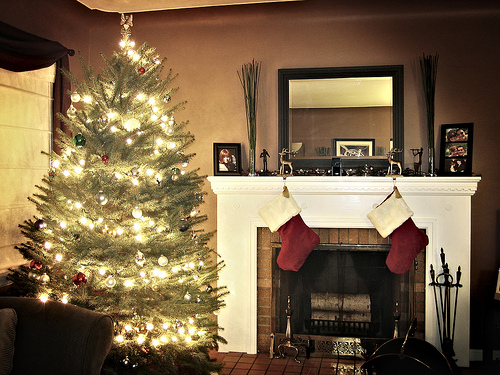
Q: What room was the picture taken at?
A: It was taken at the living room.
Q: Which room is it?
A: It is a living room.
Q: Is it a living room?
A: Yes, it is a living room.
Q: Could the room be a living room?
A: Yes, it is a living room.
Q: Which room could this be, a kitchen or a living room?
A: It is a living room.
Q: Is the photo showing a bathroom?
A: No, the picture is showing a living room.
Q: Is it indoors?
A: Yes, it is indoors.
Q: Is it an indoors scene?
A: Yes, it is indoors.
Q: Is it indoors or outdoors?
A: It is indoors.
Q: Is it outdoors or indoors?
A: It is indoors.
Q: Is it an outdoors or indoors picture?
A: It is indoors.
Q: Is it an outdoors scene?
A: No, it is indoors.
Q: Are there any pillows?
A: No, there are no pillows.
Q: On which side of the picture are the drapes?
A: The drapes are on the left of the image.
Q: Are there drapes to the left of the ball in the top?
A: Yes, there are drapes to the left of the ball.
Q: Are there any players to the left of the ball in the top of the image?
A: No, there are drapes to the left of the ball.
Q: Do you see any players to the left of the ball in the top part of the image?
A: No, there are drapes to the left of the ball.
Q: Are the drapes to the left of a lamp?
A: No, the drapes are to the left of the ball.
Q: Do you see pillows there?
A: No, there are no pillows.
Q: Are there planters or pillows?
A: No, there are no pillows or planters.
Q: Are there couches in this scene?
A: Yes, there is a couch.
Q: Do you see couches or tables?
A: Yes, there is a couch.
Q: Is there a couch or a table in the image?
A: Yes, there is a couch.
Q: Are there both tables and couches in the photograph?
A: No, there is a couch but no tables.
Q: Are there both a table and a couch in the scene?
A: No, there is a couch but no tables.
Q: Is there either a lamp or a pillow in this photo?
A: No, there are no pillows or lamps.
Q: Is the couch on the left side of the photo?
A: Yes, the couch is on the left of the image.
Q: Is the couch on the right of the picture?
A: No, the couch is on the left of the image.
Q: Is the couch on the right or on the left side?
A: The couch is on the left of the image.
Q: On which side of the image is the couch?
A: The couch is on the left of the image.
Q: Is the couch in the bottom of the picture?
A: Yes, the couch is in the bottom of the image.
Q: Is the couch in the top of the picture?
A: No, the couch is in the bottom of the image.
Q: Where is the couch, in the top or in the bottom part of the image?
A: The couch is in the bottom of the image.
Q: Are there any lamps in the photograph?
A: No, there are no lamps.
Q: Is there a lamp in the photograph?
A: No, there are no lamps.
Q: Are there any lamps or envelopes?
A: No, there are no lamps or envelopes.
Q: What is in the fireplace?
A: The logs are in the fireplace.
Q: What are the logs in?
A: The logs are in the fireplace.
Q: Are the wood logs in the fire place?
A: Yes, the logs are in the fire place.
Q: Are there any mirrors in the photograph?
A: Yes, there is a mirror.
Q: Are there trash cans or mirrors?
A: Yes, there is a mirror.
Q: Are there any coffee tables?
A: No, there are no coffee tables.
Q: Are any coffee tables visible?
A: No, there are no coffee tables.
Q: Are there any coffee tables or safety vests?
A: No, there are no coffee tables or safety vests.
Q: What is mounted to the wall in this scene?
A: The mirror is mounted to the wall.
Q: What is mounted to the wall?
A: The mirror is mounted to the wall.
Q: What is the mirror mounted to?
A: The mirror is mounted to the wall.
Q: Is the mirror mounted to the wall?
A: Yes, the mirror is mounted to the wall.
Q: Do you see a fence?
A: No, there are no fences.